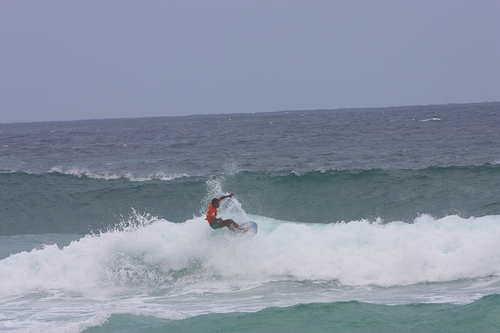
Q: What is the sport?
A: Surfing.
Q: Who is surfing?
A: A man.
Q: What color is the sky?
A: Gray.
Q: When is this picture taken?
A: During the day.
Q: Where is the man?
A: On the water.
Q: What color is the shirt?
A: Red.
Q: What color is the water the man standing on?
A: White.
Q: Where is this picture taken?
A: In an ocean.